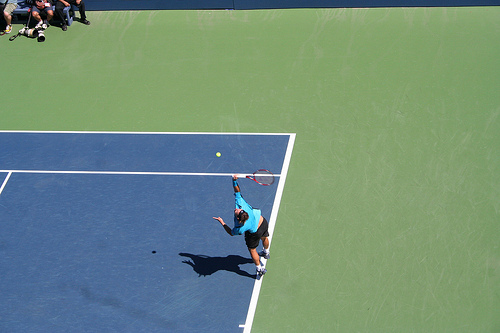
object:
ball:
[216, 152, 222, 158]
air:
[0, 1, 499, 332]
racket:
[231, 168, 274, 187]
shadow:
[178, 251, 261, 280]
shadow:
[150, 250, 157, 254]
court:
[2, 132, 297, 333]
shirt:
[232, 191, 262, 235]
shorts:
[245, 217, 270, 249]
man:
[215, 177, 271, 279]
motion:
[210, 174, 293, 280]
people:
[28, 0, 53, 27]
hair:
[237, 210, 249, 224]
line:
[3, 130, 296, 139]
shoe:
[258, 251, 271, 259]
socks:
[256, 262, 263, 273]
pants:
[244, 216, 270, 252]